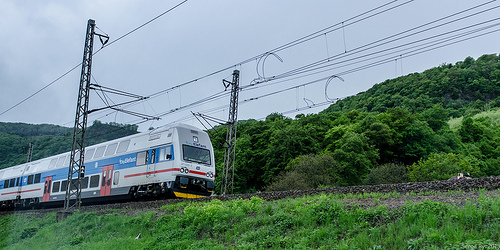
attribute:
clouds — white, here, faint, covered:
[23, 25, 96, 75]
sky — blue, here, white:
[124, 34, 247, 74]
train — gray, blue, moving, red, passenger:
[73, 133, 217, 198]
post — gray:
[75, 50, 96, 129]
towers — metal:
[215, 60, 252, 184]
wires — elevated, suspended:
[206, 50, 354, 100]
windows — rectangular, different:
[84, 142, 129, 152]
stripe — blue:
[88, 151, 157, 179]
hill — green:
[152, 190, 322, 227]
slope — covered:
[23, 124, 75, 150]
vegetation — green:
[307, 82, 422, 134]